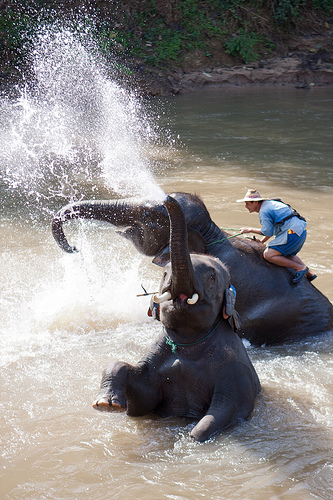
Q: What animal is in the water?
A: Elephant.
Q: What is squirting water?
A: Trunk.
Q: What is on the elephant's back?
A: A man.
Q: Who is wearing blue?
A: The man.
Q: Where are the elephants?
A: In the water.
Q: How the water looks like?
A: Brown.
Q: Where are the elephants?
A: In water.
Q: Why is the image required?
A: Remembrance.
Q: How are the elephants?
A: Gray.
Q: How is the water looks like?
A: Brown.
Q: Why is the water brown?
A: Dirt.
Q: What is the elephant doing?
A: Splashing.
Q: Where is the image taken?
A: Riverside.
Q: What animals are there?
A: Elephants.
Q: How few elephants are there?
A: 2.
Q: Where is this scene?
A: Watering hole.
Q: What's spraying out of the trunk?
A: Water.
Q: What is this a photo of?
A: Elephants bathing.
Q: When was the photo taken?
A: Daytime.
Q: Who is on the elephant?
A: A man.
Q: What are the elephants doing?
A: Bathing.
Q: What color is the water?
A: Brown.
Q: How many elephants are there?
A: Two.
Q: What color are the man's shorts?
A: Blue.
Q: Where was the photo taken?
A: On a river.